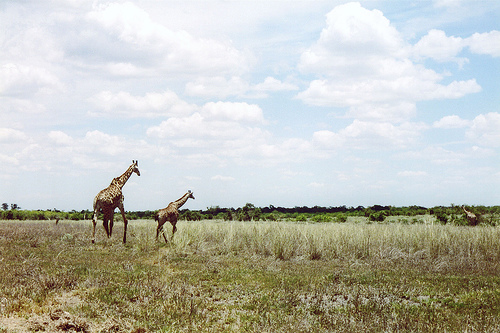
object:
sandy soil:
[2, 304, 86, 331]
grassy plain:
[1, 217, 498, 329]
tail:
[89, 198, 101, 222]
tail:
[154, 211, 159, 222]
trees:
[0, 201, 10, 212]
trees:
[425, 206, 449, 227]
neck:
[114, 168, 136, 187]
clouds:
[1, 120, 131, 210]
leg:
[115, 203, 130, 245]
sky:
[0, 0, 500, 211]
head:
[129, 158, 142, 178]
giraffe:
[88, 157, 147, 249]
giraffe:
[148, 188, 199, 250]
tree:
[369, 204, 392, 223]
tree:
[335, 213, 350, 222]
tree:
[295, 212, 309, 222]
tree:
[233, 202, 264, 223]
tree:
[265, 212, 280, 221]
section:
[242, 100, 338, 149]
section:
[332, 223, 397, 252]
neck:
[169, 196, 189, 210]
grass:
[0, 214, 500, 333]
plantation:
[0, 192, 500, 333]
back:
[84, 191, 118, 247]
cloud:
[322, 0, 497, 95]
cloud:
[0, 0, 158, 104]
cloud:
[329, 127, 496, 209]